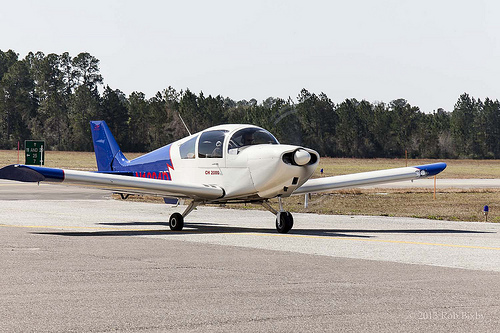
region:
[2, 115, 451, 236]
The plane is blue and white.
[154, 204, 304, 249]
The plane has wheels.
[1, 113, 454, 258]
The plane is on the ground.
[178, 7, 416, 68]
The sky is blue and white.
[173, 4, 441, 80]
The sky is cloudy.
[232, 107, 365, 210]
The plane has a propeller.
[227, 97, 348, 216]
The plane is running.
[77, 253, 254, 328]
The asphalt is gray.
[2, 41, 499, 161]
Trees are in the background.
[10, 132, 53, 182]
A sign.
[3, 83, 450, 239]
one small plane on runway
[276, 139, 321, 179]
nose of white plane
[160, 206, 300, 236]
two black plane wheels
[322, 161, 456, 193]
one white and blue plane wing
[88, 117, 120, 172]
blue tail section of plane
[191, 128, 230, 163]
one side window of small plane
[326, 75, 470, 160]
dark green trees with gray sky in background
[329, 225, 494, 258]
yellow line on airport runway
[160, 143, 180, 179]
blue,red, and white coloring on airplane body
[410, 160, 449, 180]
bright blue tip of airplane wing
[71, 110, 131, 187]
Tail of plane is blue.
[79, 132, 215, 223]
Back end of plane is blue.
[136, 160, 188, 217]
Red writing on back end of plane.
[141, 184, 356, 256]
Plane has black wheels.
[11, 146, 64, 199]
Blue on the tip of wing.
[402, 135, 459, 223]
Blue on the tip of wing.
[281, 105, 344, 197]
Propeller on front of plane is spinning.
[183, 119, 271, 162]
Front of plane is white.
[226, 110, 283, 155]
Large clear windshield on front of plane.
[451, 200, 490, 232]
Blue light on side of runway.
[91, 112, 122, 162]
Tail of plane is blue.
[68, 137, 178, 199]
Back end of plane is blue.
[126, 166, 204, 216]
Red writing on back of plane.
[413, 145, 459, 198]
Tip of wing is blue.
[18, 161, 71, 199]
Tip of wing is blue.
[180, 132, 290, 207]
Front of plane is white.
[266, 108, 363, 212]
Propeller on plane is moving.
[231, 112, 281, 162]
Clear windshield on front of plane.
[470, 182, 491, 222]
Blue light on side of runway.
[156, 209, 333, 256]
Black wheels on plane.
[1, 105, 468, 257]
a small aircraft with blue and white color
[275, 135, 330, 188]
a plane propeller in motion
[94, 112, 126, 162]
a vertical stabilizer of the plane painted in blue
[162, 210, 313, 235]
the landing gear of the plane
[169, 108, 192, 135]
the radio antenna of the aircraft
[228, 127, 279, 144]
the front window of the aircraft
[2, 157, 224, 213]
the right wing of the aircraft, painted blue and white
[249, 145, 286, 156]
a location of the engine of the plane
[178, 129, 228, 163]
two windows on the right side of the plane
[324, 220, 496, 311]
a runway